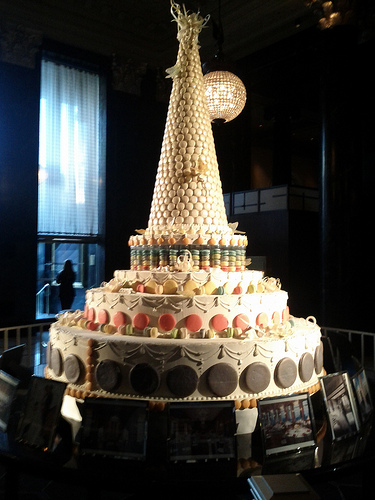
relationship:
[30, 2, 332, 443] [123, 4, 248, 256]
cake has pointed top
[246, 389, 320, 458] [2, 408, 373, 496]
picture on table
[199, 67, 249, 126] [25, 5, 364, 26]
chandelier hanging from ceiling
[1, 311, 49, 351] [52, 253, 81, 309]
railing next to person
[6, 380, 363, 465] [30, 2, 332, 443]
pictures surrounding cake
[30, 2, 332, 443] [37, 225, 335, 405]
cake with five layers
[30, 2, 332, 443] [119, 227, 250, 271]
cake has last level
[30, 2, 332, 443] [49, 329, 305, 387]
cake has first layer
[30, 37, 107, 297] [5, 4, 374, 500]
window in room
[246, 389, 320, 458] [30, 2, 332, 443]
picture next to cake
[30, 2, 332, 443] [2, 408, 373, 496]
cake on table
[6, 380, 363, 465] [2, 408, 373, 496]
pictures on table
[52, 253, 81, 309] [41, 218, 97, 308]
woman standing outside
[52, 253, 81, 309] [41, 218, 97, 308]
woman in doorway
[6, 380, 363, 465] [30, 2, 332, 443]
pictures around cake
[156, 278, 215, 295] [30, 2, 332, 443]
circles on cake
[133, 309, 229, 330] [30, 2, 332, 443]
orange circles on cake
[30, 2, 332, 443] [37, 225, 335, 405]
cake has 4 layers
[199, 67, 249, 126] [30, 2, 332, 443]
ball behind cake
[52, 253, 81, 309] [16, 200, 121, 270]
woman in background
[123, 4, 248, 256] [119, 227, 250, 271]
tower on top layer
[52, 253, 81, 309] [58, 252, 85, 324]
silhouette of person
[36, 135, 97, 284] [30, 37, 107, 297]
window with curtain